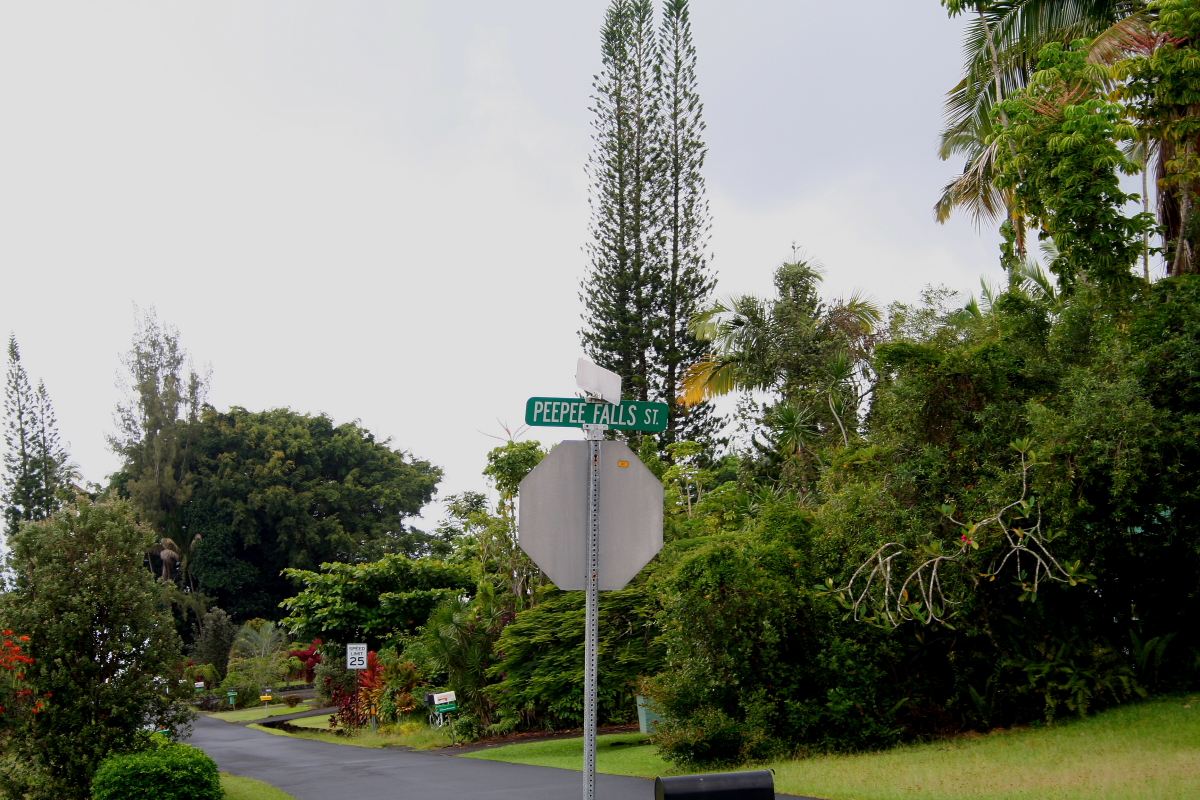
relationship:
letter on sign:
[547, 396, 564, 428] [519, 389, 688, 436]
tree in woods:
[737, 266, 848, 485] [10, 6, 1194, 793]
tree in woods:
[93, 303, 226, 580] [10, 6, 1194, 793]